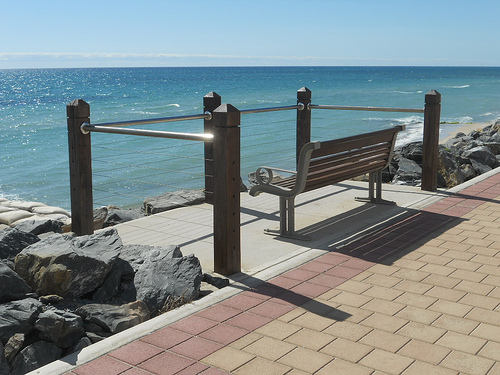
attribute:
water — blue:
[89, 74, 202, 126]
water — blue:
[2, 65, 499, 250]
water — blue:
[117, 59, 139, 126]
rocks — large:
[86, 240, 205, 317]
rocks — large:
[10, 225, 121, 300]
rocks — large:
[143, 184, 211, 214]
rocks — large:
[31, 308, 89, 343]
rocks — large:
[391, 152, 424, 182]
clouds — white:
[0, 49, 499, 69]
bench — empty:
[250, 123, 408, 238]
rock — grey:
[0, 295, 40, 337]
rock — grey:
[460, 144, 495, 164]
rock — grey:
[33, 307, 83, 346]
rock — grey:
[16, 228, 123, 295]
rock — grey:
[132, 252, 199, 313]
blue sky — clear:
[268, 7, 445, 49]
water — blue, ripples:
[0, 65, 491, 225]